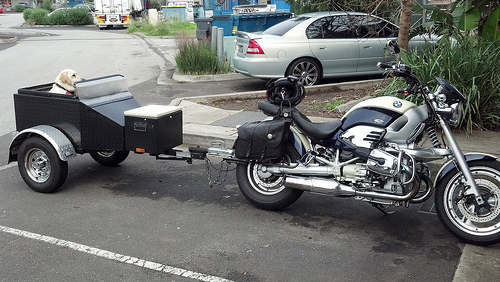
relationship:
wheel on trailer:
[15, 135, 69, 192] [4, 80, 181, 197]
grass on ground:
[379, 35, 499, 139] [2, 14, 499, 275]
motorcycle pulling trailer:
[232, 60, 500, 246] [8, 67, 232, 190]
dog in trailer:
[49, 67, 84, 97] [8, 67, 232, 190]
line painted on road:
[3, 211, 310, 278] [4, 129, 499, 279]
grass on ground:
[379, 35, 499, 132] [2, 14, 499, 275]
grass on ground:
[379, 35, 499, 132] [458, 129, 496, 151]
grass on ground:
[379, 35, 499, 132] [212, 85, 498, 141]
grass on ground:
[379, 35, 499, 132] [199, 85, 381, 116]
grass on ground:
[176, 37, 218, 75] [173, 57, 232, 79]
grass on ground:
[173, 43, 231, 77] [133, 15, 208, 75]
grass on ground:
[33, 7, 63, 26] [0, 92, 498, 279]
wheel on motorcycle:
[432, 155, 500, 247] [232, 60, 500, 246]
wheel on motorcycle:
[236, 139, 303, 204] [232, 60, 499, 246]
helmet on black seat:
[268, 69, 305, 106] [257, 100, 342, 141]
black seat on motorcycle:
[257, 100, 342, 141] [221, 35, 484, 245]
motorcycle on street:
[232, 60, 499, 246] [2, 156, 496, 276]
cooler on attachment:
[124, 100, 184, 152] [7, 76, 183, 190]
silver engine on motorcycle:
[283, 140, 421, 206] [233, 36, 498, 247]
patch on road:
[101, 219, 150, 250] [0, 12, 498, 281]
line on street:
[0, 225, 237, 282] [4, 181, 328, 279]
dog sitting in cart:
[49, 67, 87, 97] [10, 62, 130, 162]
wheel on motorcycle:
[413, 142, 497, 252] [207, 57, 495, 229]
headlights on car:
[226, 29, 260, 55] [231, 9, 461, 84]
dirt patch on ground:
[223, 91, 249, 106] [2, 14, 499, 275]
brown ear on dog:
[58, 72, 71, 84] [46, 65, 84, 97]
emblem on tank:
[285, 64, 483, 166] [326, 87, 436, 157]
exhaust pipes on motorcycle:
[264, 146, 414, 208] [232, 60, 500, 246]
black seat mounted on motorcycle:
[247, 91, 348, 141] [221, 35, 484, 245]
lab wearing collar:
[45, 67, 80, 106] [50, 80, 70, 91]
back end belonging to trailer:
[94, 0, 131, 23] [94, 2, 137, 27]